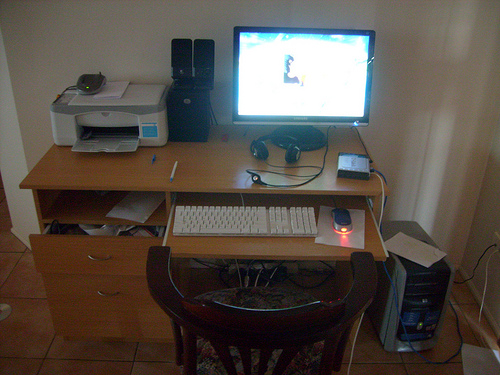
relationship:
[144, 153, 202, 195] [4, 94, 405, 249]
pen on desk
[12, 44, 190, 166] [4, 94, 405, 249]
printer on desk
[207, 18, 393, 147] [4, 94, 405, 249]
monitor on desk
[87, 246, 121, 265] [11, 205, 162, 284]
handle of drawer